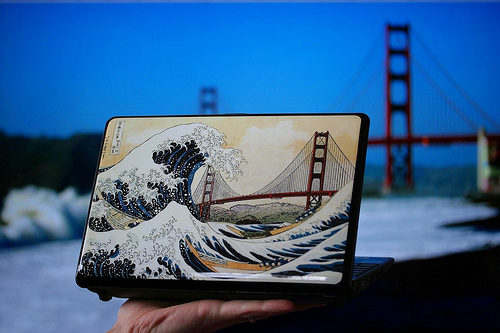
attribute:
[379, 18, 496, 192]
bridge — golden gate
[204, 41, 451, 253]
bridge — red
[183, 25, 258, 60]
sky — deep blue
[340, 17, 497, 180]
bridge — red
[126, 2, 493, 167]
sky — blue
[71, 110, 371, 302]
computer — open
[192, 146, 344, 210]
bridge — golden gate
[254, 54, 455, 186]
bridge — above